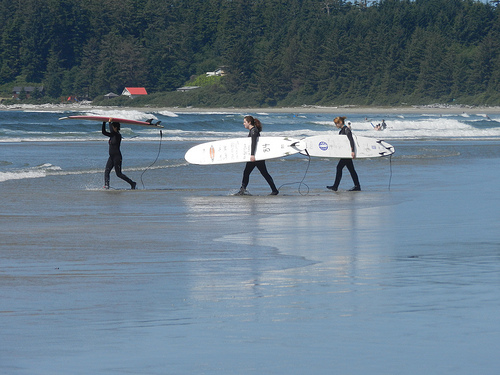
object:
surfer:
[101, 117, 135, 189]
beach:
[0, 177, 500, 374]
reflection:
[250, 201, 260, 304]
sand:
[0, 196, 499, 374]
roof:
[125, 88, 147, 95]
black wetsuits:
[101, 122, 133, 186]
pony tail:
[244, 116, 262, 131]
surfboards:
[184, 136, 306, 164]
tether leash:
[277, 149, 309, 196]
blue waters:
[0, 111, 237, 130]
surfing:
[68, 114, 150, 190]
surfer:
[236, 116, 279, 195]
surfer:
[327, 117, 361, 192]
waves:
[311, 119, 497, 138]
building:
[205, 66, 228, 76]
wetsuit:
[241, 128, 279, 196]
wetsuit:
[326, 126, 362, 191]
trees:
[292, 26, 322, 98]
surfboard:
[299, 135, 395, 159]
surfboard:
[59, 115, 165, 128]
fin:
[150, 119, 161, 124]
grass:
[90, 94, 500, 106]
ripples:
[1, 170, 62, 182]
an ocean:
[1, 109, 500, 138]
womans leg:
[334, 158, 348, 186]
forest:
[1, 1, 500, 106]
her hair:
[333, 116, 346, 124]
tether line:
[140, 126, 162, 187]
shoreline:
[0, 106, 499, 114]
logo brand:
[318, 141, 328, 151]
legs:
[256, 160, 277, 191]